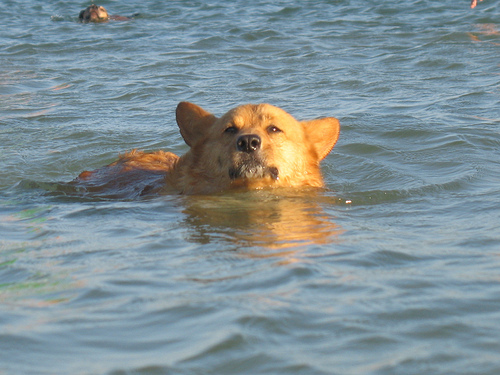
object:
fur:
[284, 140, 305, 180]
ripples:
[163, 251, 349, 324]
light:
[278, 140, 310, 172]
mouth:
[227, 157, 282, 180]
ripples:
[62, 265, 187, 309]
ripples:
[193, 299, 325, 362]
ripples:
[108, 329, 247, 373]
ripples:
[337, 157, 499, 219]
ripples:
[333, 316, 499, 374]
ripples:
[262, 205, 414, 266]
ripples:
[314, 297, 446, 363]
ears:
[308, 108, 348, 165]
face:
[213, 106, 298, 190]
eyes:
[264, 121, 286, 139]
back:
[72, 142, 182, 190]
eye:
[220, 120, 240, 138]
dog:
[46, 95, 348, 220]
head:
[171, 95, 343, 188]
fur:
[162, 150, 204, 189]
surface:
[88, 183, 482, 332]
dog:
[47, 0, 129, 31]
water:
[3, 2, 499, 372]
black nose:
[234, 132, 263, 154]